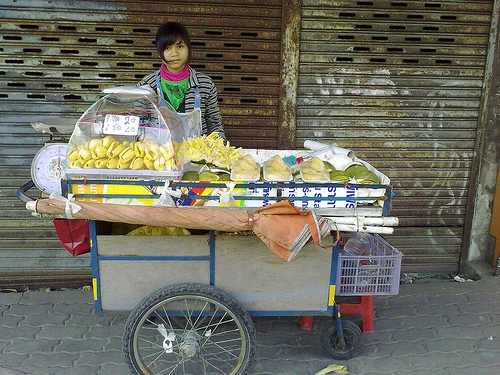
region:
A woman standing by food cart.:
[128, 31, 233, 178]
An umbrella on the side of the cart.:
[28, 195, 403, 252]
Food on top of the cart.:
[73, 125, 338, 175]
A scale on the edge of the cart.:
[24, 119, 81, 193]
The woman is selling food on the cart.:
[124, 16, 356, 228]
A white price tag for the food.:
[92, 110, 137, 147]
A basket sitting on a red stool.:
[338, 242, 429, 301]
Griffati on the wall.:
[336, 74, 474, 216]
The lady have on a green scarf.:
[138, 65, 219, 110]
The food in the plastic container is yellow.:
[71, 125, 181, 176]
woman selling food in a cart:
[7, 15, 409, 374]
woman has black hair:
[129, 9, 221, 113]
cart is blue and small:
[15, 165, 405, 372]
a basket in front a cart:
[333, 230, 411, 310]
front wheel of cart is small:
[317, 316, 368, 363]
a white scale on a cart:
[25, 120, 80, 210]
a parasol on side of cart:
[24, 189, 349, 256]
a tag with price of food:
[98, 105, 143, 139]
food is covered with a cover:
[57, 71, 189, 179]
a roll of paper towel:
[293, 131, 361, 164]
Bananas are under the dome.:
[66, 132, 182, 172]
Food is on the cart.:
[65, 128, 380, 185]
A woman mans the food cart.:
[134, 18, 226, 147]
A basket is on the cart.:
[332, 231, 403, 297]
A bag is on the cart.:
[50, 215, 95, 257]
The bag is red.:
[50, 215, 92, 258]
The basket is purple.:
[334, 232, 404, 298]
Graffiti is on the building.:
[307, 64, 482, 251]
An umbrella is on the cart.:
[20, 198, 401, 259]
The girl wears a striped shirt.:
[135, 63, 226, 145]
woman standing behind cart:
[107, 25, 235, 146]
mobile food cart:
[23, 126, 426, 373]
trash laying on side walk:
[304, 348, 349, 373]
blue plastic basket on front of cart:
[331, 225, 416, 303]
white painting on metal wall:
[318, 65, 475, 137]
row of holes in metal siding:
[311, 2, 469, 62]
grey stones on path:
[407, 290, 474, 355]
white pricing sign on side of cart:
[96, 111, 143, 136]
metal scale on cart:
[19, 114, 83, 199]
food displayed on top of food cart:
[39, 136, 400, 204]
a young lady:
[135, 18, 226, 141]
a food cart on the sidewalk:
[15, 83, 405, 370]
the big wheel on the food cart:
[126, 283, 255, 373]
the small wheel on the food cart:
[320, 320, 360, 357]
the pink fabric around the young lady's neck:
[158, 64, 192, 83]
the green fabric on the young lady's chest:
[158, 78, 193, 112]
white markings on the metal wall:
[314, 58, 485, 249]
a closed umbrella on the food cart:
[23, 196, 398, 249]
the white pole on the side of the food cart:
[322, 206, 402, 238]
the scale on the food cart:
[18, 110, 81, 200]